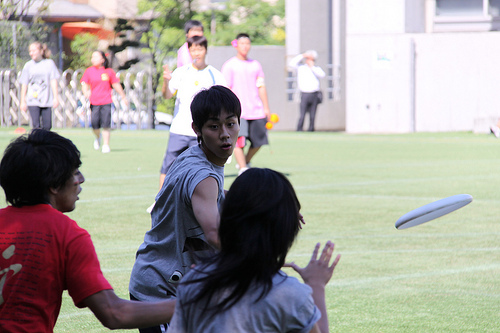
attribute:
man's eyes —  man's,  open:
[206, 119, 236, 130]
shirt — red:
[2, 196, 108, 326]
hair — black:
[0, 126, 82, 205]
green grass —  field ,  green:
[341, 145, 397, 185]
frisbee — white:
[395, 192, 473, 230]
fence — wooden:
[3, 71, 161, 131]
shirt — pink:
[225, 59, 264, 120]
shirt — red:
[169, 259, 324, 332]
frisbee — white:
[389, 182, 476, 232]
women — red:
[82, 40, 140, 147]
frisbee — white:
[396, 188, 475, 238]